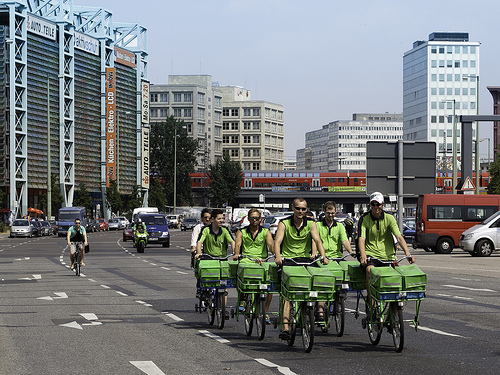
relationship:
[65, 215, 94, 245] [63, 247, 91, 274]
person riding a bicycle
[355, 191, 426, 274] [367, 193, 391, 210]
man wearing hat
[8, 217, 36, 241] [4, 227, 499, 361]
vehicle on street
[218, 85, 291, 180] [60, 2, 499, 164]
building in background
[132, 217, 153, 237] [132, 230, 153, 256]
man riding motorcycle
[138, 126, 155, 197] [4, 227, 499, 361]
sign on street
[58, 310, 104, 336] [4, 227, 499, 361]
arrow painted on street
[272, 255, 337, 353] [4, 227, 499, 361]
bicycle going down street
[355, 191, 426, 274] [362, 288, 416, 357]
man riding a bicycle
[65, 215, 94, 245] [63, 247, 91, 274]
person riding bicycle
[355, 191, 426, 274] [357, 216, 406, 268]
man wearing shirt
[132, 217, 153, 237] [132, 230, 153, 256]
man riding a motorcycle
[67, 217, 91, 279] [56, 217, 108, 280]
man riding alone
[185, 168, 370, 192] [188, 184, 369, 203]
train on bridge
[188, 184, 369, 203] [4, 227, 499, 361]
bridge over street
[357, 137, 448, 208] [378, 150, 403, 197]
board has back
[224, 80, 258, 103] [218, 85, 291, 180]
mast on top of building